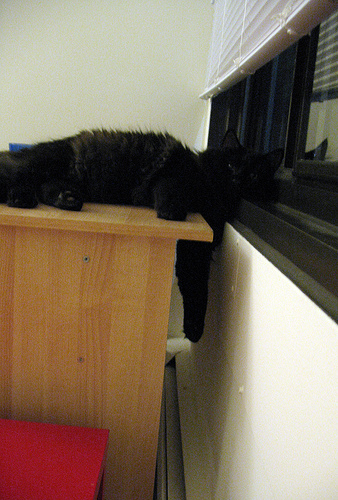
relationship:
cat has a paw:
[0, 123, 287, 343] [173, 208, 214, 343]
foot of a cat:
[52, 180, 83, 209] [0, 123, 287, 343]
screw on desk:
[80, 253, 91, 264] [0, 203, 213, 498]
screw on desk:
[75, 355, 86, 363] [0, 203, 213, 498]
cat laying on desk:
[0, 123, 287, 343] [0, 203, 213, 498]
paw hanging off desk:
[183, 320, 205, 342] [0, 203, 213, 498]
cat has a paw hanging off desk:
[0, 123, 287, 343] [0, 203, 213, 498]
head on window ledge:
[203, 132, 287, 204] [204, 178, 336, 313]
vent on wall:
[159, 329, 208, 374] [182, 0, 336, 495]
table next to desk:
[0, 417, 110, 496] [1, 412, 116, 496]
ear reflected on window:
[312, 138, 328, 161] [303, 12, 336, 162]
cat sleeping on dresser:
[9, 126, 266, 222] [1, 201, 214, 496]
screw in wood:
[71, 249, 103, 269] [0, 203, 220, 495]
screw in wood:
[76, 353, 83, 365] [0, 203, 220, 495]